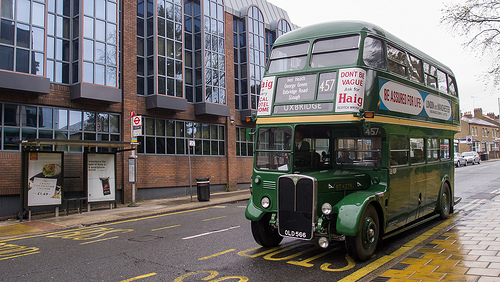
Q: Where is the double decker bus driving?
A: Down a city street.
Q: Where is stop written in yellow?
A: On tar road.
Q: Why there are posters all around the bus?
A: For advertisement.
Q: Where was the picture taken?
A: On a city street.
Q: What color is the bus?
A: Green.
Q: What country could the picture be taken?
A: United Kingdom.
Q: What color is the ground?
A: Dark grey.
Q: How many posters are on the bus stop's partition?
A: Two.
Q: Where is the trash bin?
A: Near the bus stop?.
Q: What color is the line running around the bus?
A: Yellow.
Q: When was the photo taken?
A: Daytime.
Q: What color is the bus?
A: Green.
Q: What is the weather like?
A: Rainy.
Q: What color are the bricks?
A: Yellow.